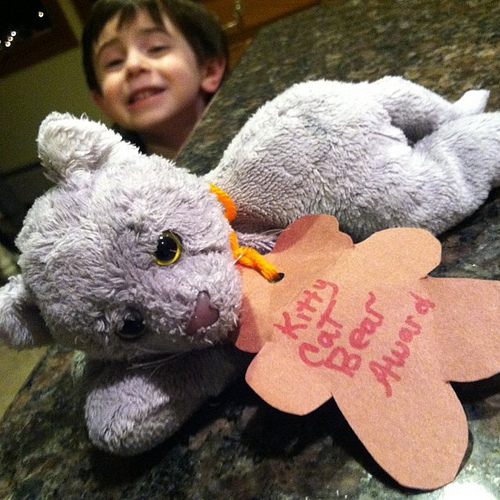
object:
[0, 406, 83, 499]
grey marble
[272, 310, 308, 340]
letter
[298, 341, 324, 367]
letter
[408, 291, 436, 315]
letter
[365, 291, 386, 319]
letter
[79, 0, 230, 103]
hair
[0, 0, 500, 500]
countertop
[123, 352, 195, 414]
whiskers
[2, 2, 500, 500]
kitchen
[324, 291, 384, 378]
bear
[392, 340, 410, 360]
letter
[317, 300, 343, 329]
letter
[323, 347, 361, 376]
letter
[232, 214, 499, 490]
note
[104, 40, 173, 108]
smile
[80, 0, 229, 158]
boy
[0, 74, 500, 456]
animal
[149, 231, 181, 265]
eye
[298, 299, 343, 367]
cat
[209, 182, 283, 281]
string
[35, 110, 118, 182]
ear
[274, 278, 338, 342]
kitty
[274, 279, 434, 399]
award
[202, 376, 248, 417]
sitting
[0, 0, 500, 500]
tabletop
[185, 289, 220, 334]
nose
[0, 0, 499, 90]
background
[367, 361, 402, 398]
letter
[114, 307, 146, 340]
eyes